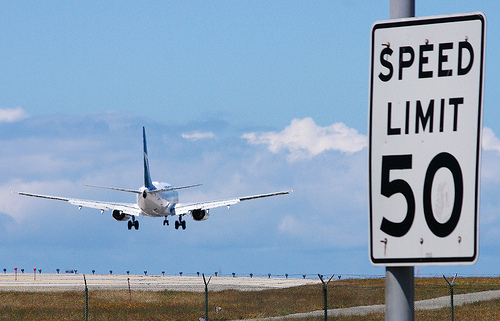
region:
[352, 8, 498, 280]
a black and white speed limit sign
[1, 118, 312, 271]
the plane is flying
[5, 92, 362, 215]
clouds in the sky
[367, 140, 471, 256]
the number 50 is black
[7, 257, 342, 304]
the runway is tan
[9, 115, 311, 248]
the plane is blue and white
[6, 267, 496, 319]
the grass is brown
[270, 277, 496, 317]
a path in the grass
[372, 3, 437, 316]
the pole is gray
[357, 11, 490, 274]
the sign is rectangular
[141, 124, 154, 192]
blue tail on white airplane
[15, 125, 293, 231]
airplane is landing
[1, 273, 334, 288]
runway under airplane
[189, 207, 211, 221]
engine under airplane wing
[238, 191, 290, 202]
dark wing panels on wing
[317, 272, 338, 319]
fence post next to fence post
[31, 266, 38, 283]
red markers on runway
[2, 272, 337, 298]
runway is gray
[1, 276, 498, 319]
grass next to runway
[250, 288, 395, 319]
paved path next to grass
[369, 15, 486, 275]
speed limit 50 sign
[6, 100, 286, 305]
plane coming in for a landing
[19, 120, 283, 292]
plane approaching the runway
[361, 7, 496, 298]
black and white sign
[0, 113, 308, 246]
white and blue airplane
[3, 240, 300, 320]
airport runway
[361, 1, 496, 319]
sign on a gray post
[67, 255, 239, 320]
chicken wire fence near a runway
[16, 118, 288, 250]
back of an airplane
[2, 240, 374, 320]
cement runway near brown field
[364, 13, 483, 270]
black and white speed limit sign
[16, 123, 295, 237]
blue and white plane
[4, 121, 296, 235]
white plane taking off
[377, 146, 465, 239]
the number "50" on sign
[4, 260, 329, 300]
tarmac with multiple reflection lights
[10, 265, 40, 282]
two red tarmac lights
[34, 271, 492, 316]
barbed fencing around airport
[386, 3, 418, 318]
grey pole holding speed limit sign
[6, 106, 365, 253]
large blue and white clouds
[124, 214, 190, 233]
three sets of wheels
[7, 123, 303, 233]
the plane is landing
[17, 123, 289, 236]
the plane is metal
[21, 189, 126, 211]
the plane is silver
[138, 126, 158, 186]
the plane is blue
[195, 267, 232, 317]
the fence is metal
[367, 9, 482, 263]
the sign is white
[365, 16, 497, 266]
the sign is black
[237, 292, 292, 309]
the grass is brown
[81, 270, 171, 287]
the runway is gray